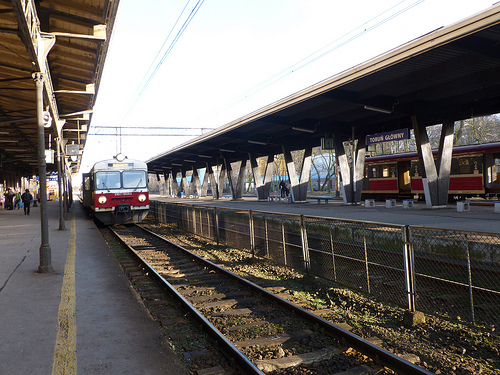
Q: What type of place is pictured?
A: It is a city.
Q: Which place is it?
A: It is a city.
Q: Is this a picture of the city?
A: Yes, it is showing the city.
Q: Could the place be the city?
A: Yes, it is the city.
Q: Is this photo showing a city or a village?
A: It is showing a city.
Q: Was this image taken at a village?
A: No, the picture was taken in a city.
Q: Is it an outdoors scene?
A: Yes, it is outdoors.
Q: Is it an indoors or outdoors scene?
A: It is outdoors.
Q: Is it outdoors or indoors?
A: It is outdoors.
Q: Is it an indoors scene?
A: No, it is outdoors.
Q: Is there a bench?
A: Yes, there is a bench.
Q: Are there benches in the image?
A: Yes, there is a bench.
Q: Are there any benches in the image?
A: Yes, there is a bench.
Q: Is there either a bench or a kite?
A: Yes, there is a bench.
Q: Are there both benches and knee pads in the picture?
A: No, there is a bench but no knee pads.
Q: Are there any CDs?
A: No, there are no cds.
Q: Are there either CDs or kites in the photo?
A: No, there are no CDs or kites.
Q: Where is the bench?
A: The bench is in the terminal.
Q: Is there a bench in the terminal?
A: Yes, there is a bench in the terminal.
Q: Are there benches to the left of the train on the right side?
A: Yes, there is a bench to the left of the train.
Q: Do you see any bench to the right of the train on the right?
A: No, the bench is to the left of the train.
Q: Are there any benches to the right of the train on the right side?
A: No, the bench is to the left of the train.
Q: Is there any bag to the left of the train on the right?
A: No, there is a bench to the left of the train.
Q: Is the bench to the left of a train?
A: Yes, the bench is to the left of a train.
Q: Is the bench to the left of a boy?
A: No, the bench is to the left of a train.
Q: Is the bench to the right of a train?
A: No, the bench is to the left of a train.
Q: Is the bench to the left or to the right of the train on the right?
A: The bench is to the left of the train.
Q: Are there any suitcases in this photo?
A: No, there are no suitcases.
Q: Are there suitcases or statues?
A: No, there are no suitcases or statues.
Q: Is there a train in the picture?
A: Yes, there is a train.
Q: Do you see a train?
A: Yes, there is a train.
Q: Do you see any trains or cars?
A: Yes, there is a train.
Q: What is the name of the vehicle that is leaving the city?
A: The vehicle is a train.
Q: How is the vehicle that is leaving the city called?
A: The vehicle is a train.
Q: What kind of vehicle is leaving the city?
A: The vehicle is a train.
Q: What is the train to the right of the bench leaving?
A: The train is leaving the city.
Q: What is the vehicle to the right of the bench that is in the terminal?
A: The vehicle is a train.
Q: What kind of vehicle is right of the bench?
A: The vehicle is a train.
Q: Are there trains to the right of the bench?
A: Yes, there is a train to the right of the bench.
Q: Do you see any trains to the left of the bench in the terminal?
A: No, the train is to the right of the bench.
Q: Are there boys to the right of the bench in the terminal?
A: No, there is a train to the right of the bench.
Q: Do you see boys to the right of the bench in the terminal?
A: No, there is a train to the right of the bench.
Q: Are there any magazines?
A: No, there are no magazines.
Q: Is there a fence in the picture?
A: Yes, there is a fence.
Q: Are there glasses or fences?
A: Yes, there is a fence.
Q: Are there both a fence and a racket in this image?
A: No, there is a fence but no rackets.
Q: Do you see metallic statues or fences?
A: Yes, there is a metal fence.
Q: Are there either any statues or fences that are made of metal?
A: Yes, the fence is made of metal.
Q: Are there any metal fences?
A: Yes, there is a fence that is made of metal.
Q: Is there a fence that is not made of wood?
A: Yes, there is a fence that is made of metal.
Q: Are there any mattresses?
A: No, there are no mattresses.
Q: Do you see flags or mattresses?
A: No, there are no mattresses or flags.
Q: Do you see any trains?
A: Yes, there is a train.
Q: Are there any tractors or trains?
A: Yes, there is a train.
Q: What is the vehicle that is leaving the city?
A: The vehicle is a train.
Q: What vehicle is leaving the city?
A: The vehicle is a train.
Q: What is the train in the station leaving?
A: The train is leaving the city.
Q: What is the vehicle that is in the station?
A: The vehicle is a train.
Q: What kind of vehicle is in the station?
A: The vehicle is a train.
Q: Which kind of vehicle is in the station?
A: The vehicle is a train.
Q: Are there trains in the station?
A: Yes, there is a train in the station.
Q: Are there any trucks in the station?
A: No, there is a train in the station.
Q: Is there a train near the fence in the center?
A: Yes, there is a train near the fence.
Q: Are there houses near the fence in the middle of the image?
A: No, there is a train near the fence.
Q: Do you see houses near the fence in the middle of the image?
A: No, there is a train near the fence.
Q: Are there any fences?
A: Yes, there is a fence.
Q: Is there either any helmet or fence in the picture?
A: Yes, there is a fence.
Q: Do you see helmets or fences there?
A: Yes, there is a fence.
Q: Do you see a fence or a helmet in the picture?
A: Yes, there is a fence.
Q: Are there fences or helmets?
A: Yes, there is a fence.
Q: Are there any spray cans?
A: No, there are no spray cans.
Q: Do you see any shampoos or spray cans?
A: No, there are no spray cans or shampoos.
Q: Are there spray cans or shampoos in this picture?
A: No, there are no spray cans or shampoos.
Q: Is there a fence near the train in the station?
A: Yes, there is a fence near the train.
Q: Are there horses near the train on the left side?
A: No, there is a fence near the train.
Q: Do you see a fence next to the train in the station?
A: Yes, there is a fence next to the train.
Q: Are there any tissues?
A: No, there are no tissues.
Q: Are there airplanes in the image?
A: No, there are no airplanes.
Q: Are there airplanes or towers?
A: No, there are no airplanes or towers.